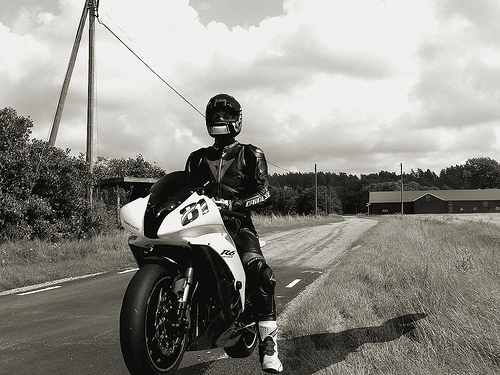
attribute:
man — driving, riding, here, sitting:
[186, 92, 268, 193]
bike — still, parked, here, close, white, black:
[116, 191, 234, 327]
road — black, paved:
[272, 226, 342, 285]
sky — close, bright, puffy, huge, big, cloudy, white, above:
[253, 20, 429, 123]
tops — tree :
[12, 109, 480, 180]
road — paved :
[23, 217, 370, 368]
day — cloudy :
[6, 4, 484, 172]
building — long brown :
[372, 175, 482, 218]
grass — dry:
[334, 223, 464, 355]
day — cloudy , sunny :
[14, 4, 484, 189]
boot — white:
[254, 310, 296, 371]